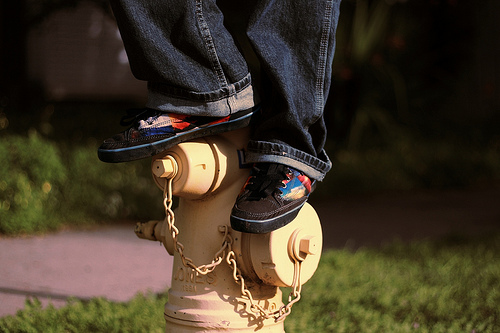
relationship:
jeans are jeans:
[114, 0, 341, 181] [259, 37, 319, 139]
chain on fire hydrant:
[152, 179, 303, 324] [125, 120, 333, 332]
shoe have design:
[97, 109, 255, 162] [138, 111, 198, 131]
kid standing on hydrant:
[100, 0, 343, 234] [136, 123, 322, 333]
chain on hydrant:
[162, 179, 227, 276] [133, 146, 294, 325]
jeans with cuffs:
[178, 42, 450, 123] [145, 75, 256, 117]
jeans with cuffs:
[178, 42, 450, 123] [238, 139, 333, 182]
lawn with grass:
[1, 222, 498, 331] [350, 239, 482, 325]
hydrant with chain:
[128, 109, 327, 331] [152, 179, 303, 324]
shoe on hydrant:
[225, 160, 317, 236] [128, 109, 327, 331]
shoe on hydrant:
[97, 109, 255, 162] [128, 109, 327, 331]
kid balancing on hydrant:
[100, 0, 343, 234] [128, 109, 327, 331]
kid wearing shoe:
[85, 0, 346, 235] [225, 160, 317, 236]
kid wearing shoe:
[85, 0, 346, 235] [89, 102, 261, 165]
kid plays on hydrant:
[85, 0, 346, 235] [128, 109, 327, 331]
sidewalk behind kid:
[47, 242, 175, 302] [100, 0, 343, 234]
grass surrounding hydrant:
[14, 114, 488, 329] [128, 109, 327, 331]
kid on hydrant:
[100, 0, 343, 234] [142, 180, 224, 321]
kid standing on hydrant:
[100, 0, 343, 234] [128, 109, 327, 331]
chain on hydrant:
[164, 187, 306, 322] [153, 117, 330, 331]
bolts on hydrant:
[124, 155, 320, 275] [106, 97, 363, 328]